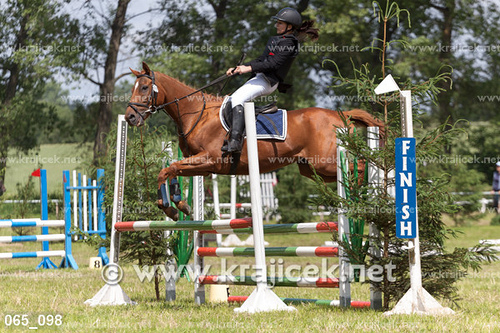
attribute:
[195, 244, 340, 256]
pole — white, red, green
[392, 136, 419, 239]
sign — blue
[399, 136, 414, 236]
word — white